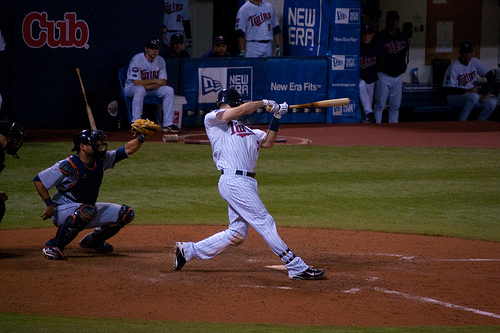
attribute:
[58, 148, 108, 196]
vest — protective, blue, red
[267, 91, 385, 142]
bat — brown, red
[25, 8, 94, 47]
letter — red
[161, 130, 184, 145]
can — white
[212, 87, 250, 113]
hat — backward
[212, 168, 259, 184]
belt — black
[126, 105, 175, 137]
mit — brown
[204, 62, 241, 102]
white symbol — blue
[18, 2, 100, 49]
print — bold, red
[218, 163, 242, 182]
loop — white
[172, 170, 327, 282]
pants — white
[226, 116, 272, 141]
print — red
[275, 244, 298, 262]
bands — double, black